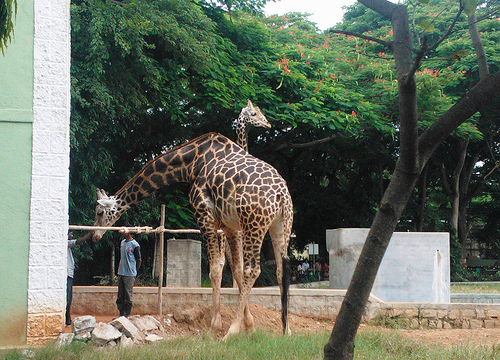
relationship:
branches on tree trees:
[406, 0, 464, 78] [321, 0, 498, 359]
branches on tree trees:
[328, 27, 395, 52] [321, 0, 498, 359]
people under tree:
[245, 4, 480, 239] [311, 258, 323, 285]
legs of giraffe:
[176, 221, 314, 358] [76, 110, 343, 358]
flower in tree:
[278, 59, 290, 76] [236, 0, 470, 280]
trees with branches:
[70, 0, 497, 359] [322, 0, 499, 359]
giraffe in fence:
[92, 124, 300, 343] [72, 231, 499, 284]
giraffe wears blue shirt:
[102, 124, 313, 279] [115, 237, 141, 275]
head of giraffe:
[241, 102, 271, 127] [230, 95, 272, 156]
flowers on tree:
[263, 49, 320, 95] [291, 67, 361, 143]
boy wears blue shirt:
[114, 229, 140, 312] [114, 237, 142, 279]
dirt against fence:
[169, 300, 373, 340] [85, 245, 445, 343]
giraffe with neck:
[92, 124, 300, 343] [80, 135, 174, 280]